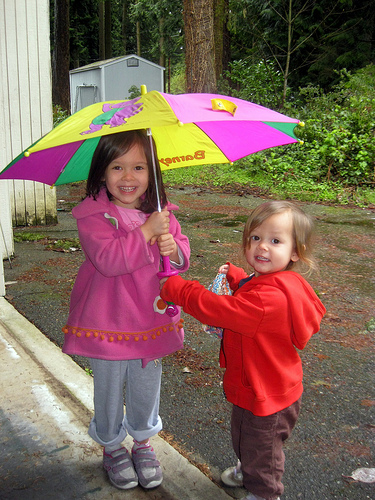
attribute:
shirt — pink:
[61, 185, 193, 368]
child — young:
[158, 200, 326, 498]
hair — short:
[239, 199, 318, 277]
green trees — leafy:
[309, 89, 372, 176]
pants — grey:
[84, 342, 166, 454]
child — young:
[156, 198, 308, 498]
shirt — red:
[165, 262, 319, 415]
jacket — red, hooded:
[159, 260, 328, 416]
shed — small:
[68, 56, 168, 116]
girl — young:
[61, 121, 190, 488]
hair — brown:
[84, 128, 165, 212]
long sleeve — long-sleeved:
[62, 185, 190, 366]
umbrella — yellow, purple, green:
[1, 79, 310, 320]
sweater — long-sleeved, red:
[169, 266, 329, 416]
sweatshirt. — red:
[160, 260, 327, 414]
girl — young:
[34, 93, 204, 414]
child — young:
[216, 213, 328, 409]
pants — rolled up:
[86, 355, 163, 446]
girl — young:
[73, 131, 183, 483]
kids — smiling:
[56, 123, 328, 498]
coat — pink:
[66, 182, 197, 367]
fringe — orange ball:
[61, 320, 187, 343]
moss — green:
[311, 204, 373, 257]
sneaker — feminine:
[94, 432, 173, 497]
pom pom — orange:
[82, 327, 93, 340]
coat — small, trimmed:
[65, 191, 186, 364]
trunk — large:
[181, 0, 221, 94]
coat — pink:
[54, 184, 195, 355]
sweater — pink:
[55, 186, 187, 360]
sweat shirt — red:
[172, 261, 335, 413]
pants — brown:
[220, 382, 305, 497]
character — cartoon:
[75, 94, 148, 133]